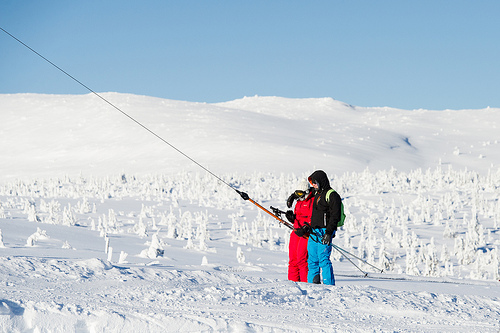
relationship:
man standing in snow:
[284, 175, 315, 283] [3, 91, 498, 331]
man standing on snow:
[275, 203, 305, 257] [130, 174, 215, 258]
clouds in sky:
[1, 0, 499, 110] [1, 0, 498, 107]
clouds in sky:
[1, 0, 499, 110] [311, 14, 376, 92]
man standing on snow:
[306, 167, 344, 282] [3, 91, 498, 331]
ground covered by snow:
[0, 178, 499, 333] [3, 91, 498, 331]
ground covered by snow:
[0, 178, 499, 333] [150, 274, 431, 330]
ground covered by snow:
[105, 259, 187, 333] [3, 91, 498, 331]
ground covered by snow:
[0, 178, 499, 333] [112, 235, 182, 324]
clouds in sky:
[1, 0, 499, 110] [130, 55, 280, 138]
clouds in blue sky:
[1, 0, 499, 110] [0, 0, 500, 110]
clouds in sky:
[241, 32, 421, 122] [12, 6, 499, 156]